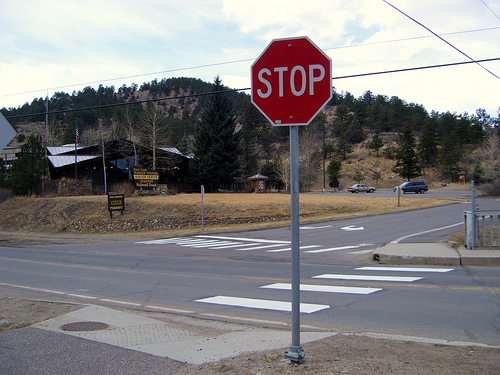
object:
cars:
[348, 181, 376, 193]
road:
[222, 203, 468, 276]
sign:
[248, 36, 333, 129]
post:
[286, 130, 308, 364]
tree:
[191, 75, 251, 189]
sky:
[5, 3, 498, 78]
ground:
[264, 338, 499, 375]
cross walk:
[197, 259, 436, 324]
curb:
[362, 237, 492, 277]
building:
[46, 137, 194, 191]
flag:
[71, 119, 82, 144]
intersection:
[63, 229, 381, 328]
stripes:
[190, 290, 324, 317]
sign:
[106, 193, 129, 216]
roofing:
[49, 154, 95, 170]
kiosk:
[246, 172, 271, 193]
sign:
[127, 165, 163, 191]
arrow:
[341, 220, 364, 238]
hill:
[117, 73, 228, 145]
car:
[394, 179, 430, 194]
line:
[258, 282, 381, 295]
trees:
[70, 85, 93, 122]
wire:
[349, 57, 495, 80]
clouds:
[7, 3, 499, 37]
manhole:
[55, 317, 111, 341]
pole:
[320, 123, 329, 190]